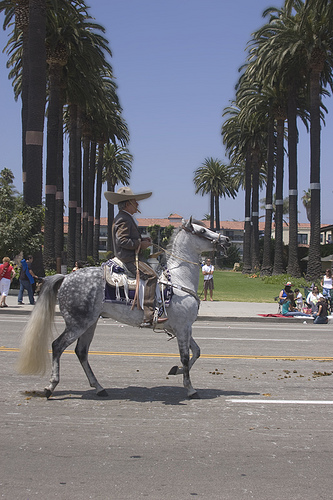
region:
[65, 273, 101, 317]
this is a horse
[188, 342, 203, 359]
the knee is bent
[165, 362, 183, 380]
the hoof is lifted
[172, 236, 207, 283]
the horse is white in color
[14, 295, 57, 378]
the tail is long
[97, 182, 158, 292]
a man is on the back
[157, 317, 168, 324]
this is the shoe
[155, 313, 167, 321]
the shoe is brown in color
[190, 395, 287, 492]
the road is tarmacked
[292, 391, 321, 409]
white strip is on the middle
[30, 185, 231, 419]
dappled gray horse prancing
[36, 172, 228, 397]
man in hat riding a horse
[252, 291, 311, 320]
person with long hair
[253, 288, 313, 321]
person sitting on a red blanket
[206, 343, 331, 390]
horse poop in road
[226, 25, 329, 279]
row of six palm trees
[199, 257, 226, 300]
man in white shirt and shorts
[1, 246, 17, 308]
person with red shirt and white pants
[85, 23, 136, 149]
palm tree branches and sky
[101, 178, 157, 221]
profile of head with big hat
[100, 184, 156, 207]
Sombrero worn by older man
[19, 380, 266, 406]
Shadow cast on the ground by a horse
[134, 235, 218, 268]
Reigns on a horse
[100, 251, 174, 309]
Saddle on a horse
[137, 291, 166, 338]
Stirrups attached to saddle on a horse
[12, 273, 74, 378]
Fluffy tail of a horse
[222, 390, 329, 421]
White lines painted on the street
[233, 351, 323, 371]
Yellow lines painted on the street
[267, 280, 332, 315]
Spectators watching a parade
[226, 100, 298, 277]
Row of palm trees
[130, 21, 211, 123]
this is the sky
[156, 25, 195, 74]
the sky is blue in color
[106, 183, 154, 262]
this is a man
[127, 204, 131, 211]
the man is light skinned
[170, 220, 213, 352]
this is a horse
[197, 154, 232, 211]
this is a tree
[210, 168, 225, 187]
the leaves are green in color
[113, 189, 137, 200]
this is a hat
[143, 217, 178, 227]
this is the roof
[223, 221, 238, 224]
the roof is red in color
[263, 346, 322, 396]
horse poop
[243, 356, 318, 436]
horse poop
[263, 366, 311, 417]
horse poop